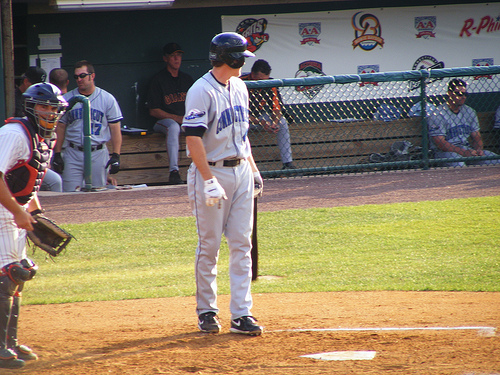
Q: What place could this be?
A: It is a field.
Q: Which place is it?
A: It is a field.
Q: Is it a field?
A: Yes, it is a field.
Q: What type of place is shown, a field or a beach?
A: It is a field.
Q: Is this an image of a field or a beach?
A: It is showing a field.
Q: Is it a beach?
A: No, it is a field.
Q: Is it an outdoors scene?
A: Yes, it is outdoors.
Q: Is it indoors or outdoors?
A: It is outdoors.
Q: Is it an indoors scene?
A: No, it is outdoors.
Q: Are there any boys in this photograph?
A: No, there are no boys.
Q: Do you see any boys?
A: No, there are no boys.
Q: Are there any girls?
A: No, there are no girls.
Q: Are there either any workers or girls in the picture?
A: No, there are no girls or workers.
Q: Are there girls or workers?
A: No, there are no girls or workers.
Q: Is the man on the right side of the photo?
A: No, the man is on the left of the image.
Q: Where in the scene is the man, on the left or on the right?
A: The man is on the left of the image.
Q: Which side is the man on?
A: The man is on the left of the image.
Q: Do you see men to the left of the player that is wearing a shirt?
A: Yes, there is a man to the left of the player.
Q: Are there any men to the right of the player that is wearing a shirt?
A: No, the man is to the left of the player.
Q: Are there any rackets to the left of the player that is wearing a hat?
A: No, there is a man to the left of the player.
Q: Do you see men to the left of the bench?
A: Yes, there is a man to the left of the bench.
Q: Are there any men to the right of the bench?
A: No, the man is to the left of the bench.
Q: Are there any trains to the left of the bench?
A: No, there is a man to the left of the bench.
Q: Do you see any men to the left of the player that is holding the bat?
A: Yes, there is a man to the left of the player.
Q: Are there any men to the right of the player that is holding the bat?
A: No, the man is to the left of the player.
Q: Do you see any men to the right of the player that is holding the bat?
A: No, the man is to the left of the player.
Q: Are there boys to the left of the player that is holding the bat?
A: No, there is a man to the left of the player.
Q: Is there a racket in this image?
A: No, there are no rackets.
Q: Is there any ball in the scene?
A: No, there are no balls.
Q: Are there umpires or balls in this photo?
A: No, there are no balls or umpires.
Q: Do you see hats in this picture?
A: Yes, there is a hat.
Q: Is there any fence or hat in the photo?
A: Yes, there is a hat.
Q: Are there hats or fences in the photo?
A: Yes, there is a hat.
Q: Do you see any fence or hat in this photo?
A: Yes, there is a hat.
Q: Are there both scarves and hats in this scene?
A: No, there is a hat but no scarves.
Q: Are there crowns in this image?
A: No, there are no crowns.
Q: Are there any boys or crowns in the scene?
A: No, there are no crowns or boys.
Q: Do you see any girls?
A: No, there are no girls.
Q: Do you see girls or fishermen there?
A: No, there are no girls or fishermen.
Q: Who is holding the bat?
A: The player is holding the bat.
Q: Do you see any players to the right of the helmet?
A: Yes, there is a player to the right of the helmet.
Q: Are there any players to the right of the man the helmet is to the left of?
A: Yes, there is a player to the right of the man.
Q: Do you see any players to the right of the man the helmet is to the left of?
A: Yes, there is a player to the right of the man.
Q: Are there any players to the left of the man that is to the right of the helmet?
A: No, the player is to the right of the man.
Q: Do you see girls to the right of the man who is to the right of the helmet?
A: No, there is a player to the right of the man.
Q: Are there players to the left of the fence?
A: Yes, there is a player to the left of the fence.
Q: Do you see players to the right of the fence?
A: No, the player is to the left of the fence.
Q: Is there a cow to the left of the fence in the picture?
A: No, there is a player to the left of the fence.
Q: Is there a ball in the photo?
A: No, there are no balls.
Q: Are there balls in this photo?
A: No, there are no balls.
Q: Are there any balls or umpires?
A: No, there are no balls or umpires.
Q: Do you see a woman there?
A: No, there are no women.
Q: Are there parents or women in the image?
A: No, there are no women or parents.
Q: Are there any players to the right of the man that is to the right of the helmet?
A: Yes, there is a player to the right of the man.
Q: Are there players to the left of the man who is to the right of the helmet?
A: No, the player is to the right of the man.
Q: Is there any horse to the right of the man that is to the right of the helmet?
A: No, there is a player to the right of the man.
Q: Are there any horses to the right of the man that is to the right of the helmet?
A: No, there is a player to the right of the man.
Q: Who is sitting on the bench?
A: The player is sitting on the bench.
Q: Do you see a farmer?
A: No, there are no farmers.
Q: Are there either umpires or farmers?
A: No, there are no farmers or umpires.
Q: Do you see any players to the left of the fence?
A: Yes, there is a player to the left of the fence.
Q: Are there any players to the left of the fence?
A: Yes, there is a player to the left of the fence.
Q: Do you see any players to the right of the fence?
A: No, the player is to the left of the fence.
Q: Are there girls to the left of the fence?
A: No, there is a player to the left of the fence.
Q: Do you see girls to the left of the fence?
A: No, there is a player to the left of the fence.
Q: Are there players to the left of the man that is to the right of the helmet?
A: No, the player is to the right of the man.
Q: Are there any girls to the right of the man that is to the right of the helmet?
A: No, there is a player to the right of the man.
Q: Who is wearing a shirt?
A: The player is wearing a shirt.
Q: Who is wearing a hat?
A: The player is wearing a hat.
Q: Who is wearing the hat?
A: The player is wearing a hat.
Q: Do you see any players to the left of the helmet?
A: No, the player is to the right of the helmet.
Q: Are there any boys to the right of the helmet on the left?
A: No, there is a player to the right of the helmet.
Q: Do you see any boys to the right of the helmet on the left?
A: No, there is a player to the right of the helmet.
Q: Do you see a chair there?
A: No, there are no chairs.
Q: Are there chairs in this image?
A: No, there are no chairs.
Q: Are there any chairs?
A: No, there are no chairs.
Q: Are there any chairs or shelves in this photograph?
A: No, there are no chairs or shelves.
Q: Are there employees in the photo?
A: No, there are no employees.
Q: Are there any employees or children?
A: No, there are no employees or children.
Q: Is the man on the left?
A: Yes, the man is on the left of the image.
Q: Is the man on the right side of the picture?
A: No, the man is on the left of the image.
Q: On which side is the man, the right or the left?
A: The man is on the left of the image.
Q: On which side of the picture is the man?
A: The man is on the left of the image.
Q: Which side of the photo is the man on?
A: The man is on the left of the image.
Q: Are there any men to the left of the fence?
A: Yes, there is a man to the left of the fence.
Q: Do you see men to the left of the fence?
A: Yes, there is a man to the left of the fence.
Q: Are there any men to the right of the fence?
A: No, the man is to the left of the fence.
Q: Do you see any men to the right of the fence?
A: No, the man is to the left of the fence.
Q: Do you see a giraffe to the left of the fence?
A: No, there is a man to the left of the fence.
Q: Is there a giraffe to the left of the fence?
A: No, there is a man to the left of the fence.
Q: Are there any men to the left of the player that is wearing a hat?
A: Yes, there is a man to the left of the player.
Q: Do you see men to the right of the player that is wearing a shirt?
A: No, the man is to the left of the player.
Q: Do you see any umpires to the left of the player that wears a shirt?
A: No, there is a man to the left of the player.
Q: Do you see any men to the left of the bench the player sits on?
A: Yes, there is a man to the left of the bench.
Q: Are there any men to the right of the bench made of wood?
A: No, the man is to the left of the bench.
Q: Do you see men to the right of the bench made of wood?
A: No, the man is to the left of the bench.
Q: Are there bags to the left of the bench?
A: No, there is a man to the left of the bench.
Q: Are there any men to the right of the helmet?
A: Yes, there is a man to the right of the helmet.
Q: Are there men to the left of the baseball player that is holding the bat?
A: Yes, there is a man to the left of the player.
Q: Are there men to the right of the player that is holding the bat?
A: No, the man is to the left of the player.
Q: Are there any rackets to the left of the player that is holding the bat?
A: No, there is a man to the left of the player.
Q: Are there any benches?
A: Yes, there is a bench.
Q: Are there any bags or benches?
A: Yes, there is a bench.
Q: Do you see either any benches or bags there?
A: Yes, there is a bench.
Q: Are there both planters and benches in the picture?
A: No, there is a bench but no planters.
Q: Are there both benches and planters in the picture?
A: No, there is a bench but no planters.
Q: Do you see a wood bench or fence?
A: Yes, there is a wood bench.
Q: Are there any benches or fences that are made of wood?
A: Yes, the bench is made of wood.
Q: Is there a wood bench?
A: Yes, there is a bench that is made of wood.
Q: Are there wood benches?
A: Yes, there is a bench that is made of wood.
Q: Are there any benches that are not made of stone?
A: Yes, there is a bench that is made of wood.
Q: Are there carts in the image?
A: No, there are no carts.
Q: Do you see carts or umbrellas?
A: No, there are no carts or umbrellas.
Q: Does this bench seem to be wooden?
A: Yes, the bench is wooden.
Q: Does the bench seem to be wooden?
A: Yes, the bench is wooden.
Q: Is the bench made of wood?
A: Yes, the bench is made of wood.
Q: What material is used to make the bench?
A: The bench is made of wood.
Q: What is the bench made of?
A: The bench is made of wood.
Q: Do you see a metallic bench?
A: No, there is a bench but it is wooden.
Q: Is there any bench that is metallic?
A: No, there is a bench but it is wooden.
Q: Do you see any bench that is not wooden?
A: No, there is a bench but it is wooden.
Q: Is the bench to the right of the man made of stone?
A: No, the bench is made of wood.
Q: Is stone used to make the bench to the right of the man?
A: No, the bench is made of wood.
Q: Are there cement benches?
A: No, there is a bench but it is made of wood.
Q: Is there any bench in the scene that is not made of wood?
A: No, there is a bench but it is made of wood.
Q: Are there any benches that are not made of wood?
A: No, there is a bench but it is made of wood.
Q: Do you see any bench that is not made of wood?
A: No, there is a bench but it is made of wood.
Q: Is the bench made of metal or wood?
A: The bench is made of wood.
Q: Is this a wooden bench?
A: Yes, this is a wooden bench.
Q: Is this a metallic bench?
A: No, this is a wooden bench.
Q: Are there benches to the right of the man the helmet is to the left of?
A: Yes, there is a bench to the right of the man.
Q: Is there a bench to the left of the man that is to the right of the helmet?
A: No, the bench is to the right of the man.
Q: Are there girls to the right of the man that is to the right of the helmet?
A: No, there is a bench to the right of the man.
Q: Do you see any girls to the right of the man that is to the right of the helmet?
A: No, there is a bench to the right of the man.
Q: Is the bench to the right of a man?
A: Yes, the bench is to the right of a man.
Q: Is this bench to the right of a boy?
A: No, the bench is to the right of a man.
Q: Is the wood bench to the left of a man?
A: No, the bench is to the right of a man.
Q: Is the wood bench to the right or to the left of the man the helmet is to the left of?
A: The bench is to the right of the man.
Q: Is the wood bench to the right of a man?
A: Yes, the bench is to the right of a man.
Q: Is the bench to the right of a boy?
A: No, the bench is to the right of a man.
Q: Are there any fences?
A: Yes, there is a fence.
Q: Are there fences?
A: Yes, there is a fence.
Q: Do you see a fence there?
A: Yes, there is a fence.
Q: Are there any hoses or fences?
A: Yes, there is a fence.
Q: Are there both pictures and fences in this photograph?
A: No, there is a fence but no pictures.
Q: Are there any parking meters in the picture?
A: No, there are no parking meters.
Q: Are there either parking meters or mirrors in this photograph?
A: No, there are no parking meters or mirrors.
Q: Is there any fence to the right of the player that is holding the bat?
A: Yes, there is a fence to the right of the player.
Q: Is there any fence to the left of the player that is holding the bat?
A: No, the fence is to the right of the player.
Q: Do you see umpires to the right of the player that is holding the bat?
A: No, there is a fence to the right of the player.